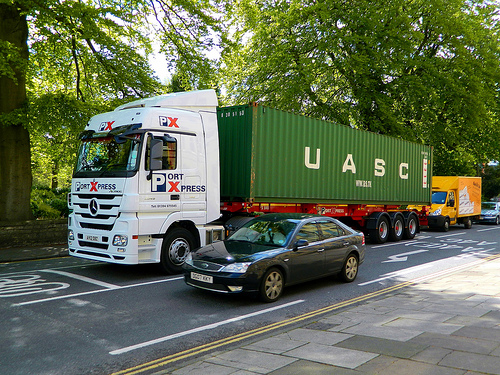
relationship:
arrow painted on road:
[384, 247, 419, 268] [4, 205, 497, 374]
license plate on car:
[188, 267, 215, 287] [172, 225, 386, 285]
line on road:
[4, 217, 496, 373] [111, 298, 307, 361]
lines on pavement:
[107, 247, 498, 372] [2, 202, 498, 370]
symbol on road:
[5, 261, 91, 315] [58, 289, 138, 348]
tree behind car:
[222, 0, 499, 102] [177, 209, 370, 303]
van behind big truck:
[420, 173, 480, 231] [40, 84, 443, 260]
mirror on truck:
[143, 132, 175, 170] [65, 83, 428, 227]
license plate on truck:
[79, 232, 104, 242] [67, 89, 432, 273]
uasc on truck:
[298, 145, 413, 184] [67, 89, 432, 273]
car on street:
[177, 209, 370, 303] [2, 223, 499, 366]